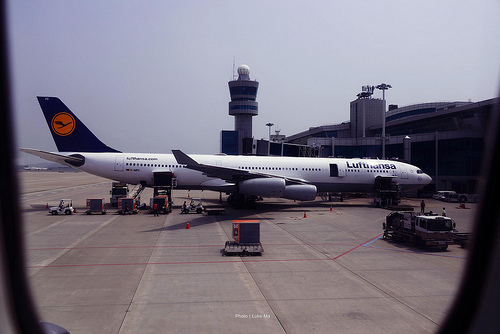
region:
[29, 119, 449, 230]
a very big aero plane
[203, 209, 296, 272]
a truck on the road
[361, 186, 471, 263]
vehicle on the airport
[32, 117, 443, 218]
a beautiful white plane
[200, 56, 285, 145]
a very big statue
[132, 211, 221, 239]
shadow of the plane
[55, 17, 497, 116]
clear view of sky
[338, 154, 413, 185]
name of the aeroplane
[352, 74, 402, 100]
a far away objects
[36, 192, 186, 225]
a group of vehicles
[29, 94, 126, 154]
a tail wing on a plane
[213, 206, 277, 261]
a luggage cart on a tarmac.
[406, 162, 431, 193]
a cock pit on a jet.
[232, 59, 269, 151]
a tower at an airport.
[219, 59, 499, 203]
an airport under a hazy sky.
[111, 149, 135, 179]
a door on the back of a jet.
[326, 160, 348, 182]
an open door.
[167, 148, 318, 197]
a large jet engine.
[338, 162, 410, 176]
a company logo.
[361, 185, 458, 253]
a truck on a tarmac.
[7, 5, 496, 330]
Photo taken from inside a plane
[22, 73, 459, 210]
White and blue plane parked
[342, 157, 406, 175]
Lufthansa plane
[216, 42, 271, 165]
Control tower at the airport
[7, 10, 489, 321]
Photo taken at an airport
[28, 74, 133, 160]
Blue and orange on the fin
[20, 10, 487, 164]
The sky is gray and hazy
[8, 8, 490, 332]
Photo taken during the day.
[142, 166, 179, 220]
baggage being loaded onto the plane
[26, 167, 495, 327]
Ground is made of concrete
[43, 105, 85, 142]
This airplane has a symbol on the back wing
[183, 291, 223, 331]
There is grey cement on the runway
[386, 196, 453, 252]
There is a baggage-handling truck here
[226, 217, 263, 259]
There is a baggage compartment on the runway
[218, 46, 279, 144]
There is an airplane tower in the distance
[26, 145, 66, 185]
There is a wing toward the back of the plane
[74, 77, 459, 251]
This is a commercial airliner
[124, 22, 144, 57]
The sky is very light blue in color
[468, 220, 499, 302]
The photo was taken out of an airplane window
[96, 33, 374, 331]
The photo was taken by Jackson Mingus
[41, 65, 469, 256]
large white and blue plane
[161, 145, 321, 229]
wing of large plane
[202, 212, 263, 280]
red truck on the tarmac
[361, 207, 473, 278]
firetruck on tarmac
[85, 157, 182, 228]
trucks next to plane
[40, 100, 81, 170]
yellow logo on tail end of plane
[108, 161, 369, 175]
windows on side of plane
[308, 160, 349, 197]
door on side of plane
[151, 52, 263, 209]
air traffic control tower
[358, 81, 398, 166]
light post sticking up